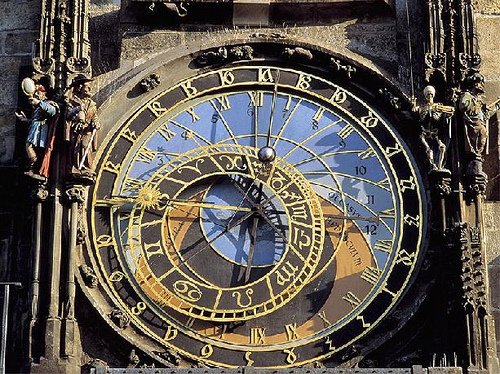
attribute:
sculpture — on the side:
[61, 72, 103, 177]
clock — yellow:
[50, 39, 434, 350]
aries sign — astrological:
[177, 158, 206, 177]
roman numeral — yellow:
[307, 102, 326, 124]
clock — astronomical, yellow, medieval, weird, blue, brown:
[68, 41, 450, 365]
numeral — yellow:
[282, 319, 302, 340]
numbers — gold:
[61, 40, 449, 372]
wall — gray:
[1, 0, 499, 371]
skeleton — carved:
[409, 59, 492, 207]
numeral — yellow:
[358, 264, 384, 285]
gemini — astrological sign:
[140, 234, 165, 261]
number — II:
[336, 120, 366, 142]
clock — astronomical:
[88, 64, 431, 367]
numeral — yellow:
[337, 120, 352, 140]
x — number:
[314, 305, 335, 330]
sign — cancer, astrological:
[165, 277, 205, 308]